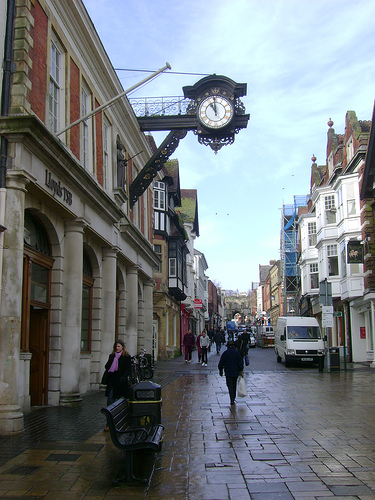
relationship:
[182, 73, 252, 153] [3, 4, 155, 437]
clock on building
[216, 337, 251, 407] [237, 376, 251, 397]
person has bag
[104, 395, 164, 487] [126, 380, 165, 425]
bench by bin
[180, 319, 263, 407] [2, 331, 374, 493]
people on pavenment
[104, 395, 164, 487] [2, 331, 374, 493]
bench on pavenment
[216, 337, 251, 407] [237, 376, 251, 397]
person holding bag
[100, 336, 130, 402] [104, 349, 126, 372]
woman wearing scarf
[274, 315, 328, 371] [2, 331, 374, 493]
truck on pavenment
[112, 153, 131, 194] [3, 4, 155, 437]
window on building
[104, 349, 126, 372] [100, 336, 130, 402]
scarf on woman